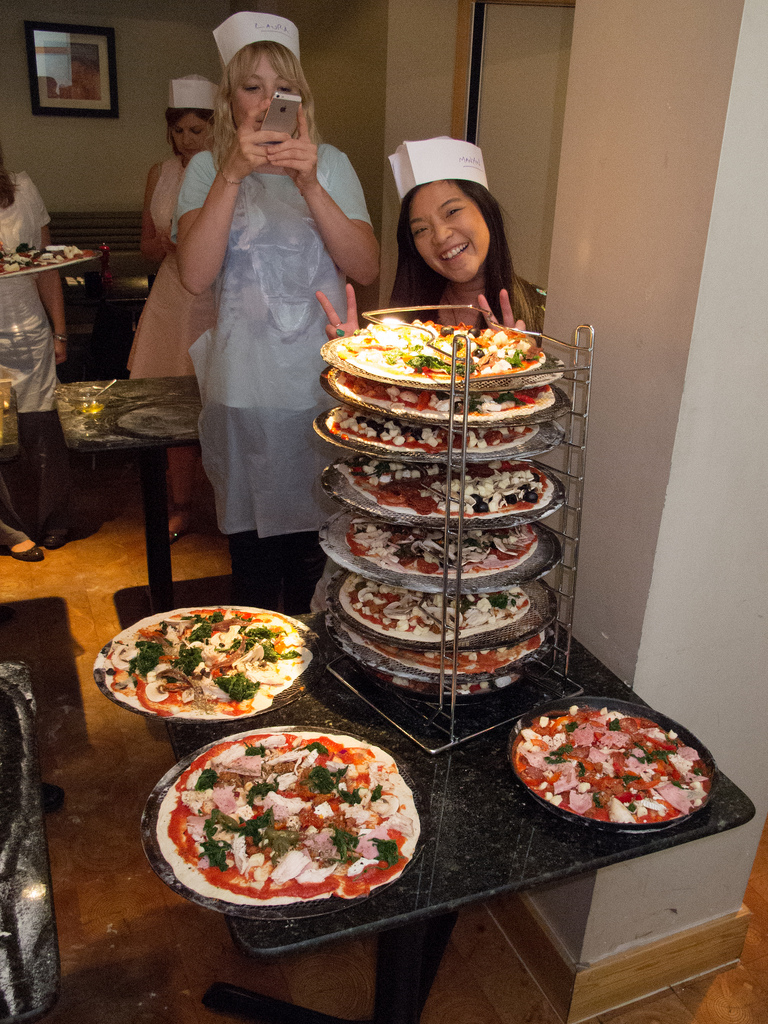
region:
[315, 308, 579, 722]
a metal tray with pizzas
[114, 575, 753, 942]
a table with pizzas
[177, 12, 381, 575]
a woman taking a picture of pizzas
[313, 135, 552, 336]
a woman posing near a table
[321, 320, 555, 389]
a pizza on a tray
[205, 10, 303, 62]
a paper hat on a girls head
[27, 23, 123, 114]
a photo on a wall in a picture frame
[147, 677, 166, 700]
a mushroom on a pizza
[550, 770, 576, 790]
ham on a pizza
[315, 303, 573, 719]
metal rack full of pizzas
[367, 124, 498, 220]
girl wearing a white paper hat giving peace signs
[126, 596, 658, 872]
black table with pizzas on it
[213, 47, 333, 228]
blonde girl taking a picture with an iphone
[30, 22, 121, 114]
black framed picture on the wall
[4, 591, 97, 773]
shadow from the table on the floor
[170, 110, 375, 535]
girl is wearing a white plastic apron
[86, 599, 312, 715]
pizza ready to be cooked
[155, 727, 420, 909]
pizza ready to be cooked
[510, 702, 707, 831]
pizza ready to be cooked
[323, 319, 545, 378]
pizza ready to be cooked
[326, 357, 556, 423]
pizza ready to be cooked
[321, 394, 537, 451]
pizza ready to be cooked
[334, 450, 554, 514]
pizza ready to be cooked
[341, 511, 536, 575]
pizza ready to be cooked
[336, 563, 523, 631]
pizza ready to be cooked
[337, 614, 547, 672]
pizza ready to be cooked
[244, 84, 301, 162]
a woman holding a cell phone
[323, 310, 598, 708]
several pizzas on a rack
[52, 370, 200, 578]
a square wood table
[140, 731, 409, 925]
a round pizza on a table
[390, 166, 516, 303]
a woman with black hair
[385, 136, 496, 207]
a woman wearing a white paper hat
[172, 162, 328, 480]
a woman wearing a plastic apron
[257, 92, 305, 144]
a silver cell phone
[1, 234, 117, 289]
a woman holding a pizza on a pan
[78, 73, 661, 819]
the pizzas are stacked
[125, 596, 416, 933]
the pizzas are raw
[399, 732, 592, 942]
the table is marble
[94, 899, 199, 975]
the ground is brown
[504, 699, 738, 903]
the pizza has meat on it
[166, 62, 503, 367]
the woman are posing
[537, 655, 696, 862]
uncooked pizza on metal tray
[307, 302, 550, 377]
uncooked pizza on metal tray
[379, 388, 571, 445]
uncooked pizza on metal tray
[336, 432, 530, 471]
uncooked pizza on metal tray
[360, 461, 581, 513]
uncooked pizza on metal tray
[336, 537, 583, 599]
uncooked pizza on metal tray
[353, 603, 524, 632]
uncooked pizza on metal tray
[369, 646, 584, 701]
uncooked pizza on metal tray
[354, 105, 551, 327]
head of the girl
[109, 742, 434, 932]
pizza on the table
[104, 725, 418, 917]
toppings on the pizza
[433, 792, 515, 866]
table under the pizza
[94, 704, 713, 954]
two pizzas near each other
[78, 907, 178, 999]
ground under the pizza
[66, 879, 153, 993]
light hitting the ground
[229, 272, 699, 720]
stack of pizzas on top of each other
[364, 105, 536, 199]
hat on the girl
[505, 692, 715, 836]
the pizza in the pan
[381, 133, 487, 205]
the chef hat is white